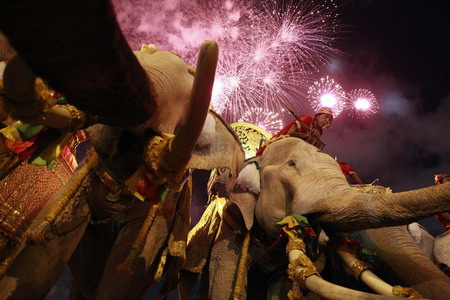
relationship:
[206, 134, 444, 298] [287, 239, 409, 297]
elephant has tusks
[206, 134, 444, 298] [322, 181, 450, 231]
elephant has a trunk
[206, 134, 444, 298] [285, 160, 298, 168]
elephant has an eye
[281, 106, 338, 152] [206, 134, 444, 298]
person riding elephant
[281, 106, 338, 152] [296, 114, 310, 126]
person wearing red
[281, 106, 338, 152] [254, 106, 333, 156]
person leaning person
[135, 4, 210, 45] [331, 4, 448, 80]
smoke in sky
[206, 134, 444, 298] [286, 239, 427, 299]
elephant has a tusks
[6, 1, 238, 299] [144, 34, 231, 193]
elephant has a tusk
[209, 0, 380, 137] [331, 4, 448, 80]
fireworks in sky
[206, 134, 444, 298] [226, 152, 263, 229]
elephant has an ear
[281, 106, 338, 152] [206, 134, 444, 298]
person riding an elephant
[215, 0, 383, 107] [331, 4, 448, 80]
fireworks i sky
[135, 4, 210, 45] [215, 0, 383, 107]
smoke from fireworks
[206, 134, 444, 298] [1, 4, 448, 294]
elephant durig festivities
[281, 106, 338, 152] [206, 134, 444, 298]
person on top of elephant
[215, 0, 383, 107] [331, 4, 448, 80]
fireworks in sky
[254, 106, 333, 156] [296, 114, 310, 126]
person wearing red